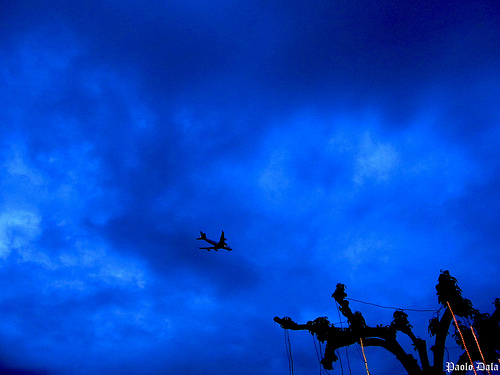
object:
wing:
[216, 230, 227, 245]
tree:
[272, 268, 499, 374]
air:
[15, 19, 478, 208]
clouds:
[0, 0, 499, 373]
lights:
[442, 296, 479, 375]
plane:
[196, 230, 234, 255]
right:
[442, 9, 485, 356]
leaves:
[442, 287, 452, 297]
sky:
[0, 0, 499, 374]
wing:
[196, 245, 217, 253]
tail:
[199, 232, 207, 240]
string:
[281, 328, 293, 373]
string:
[443, 299, 476, 374]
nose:
[222, 245, 236, 252]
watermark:
[443, 360, 499, 373]